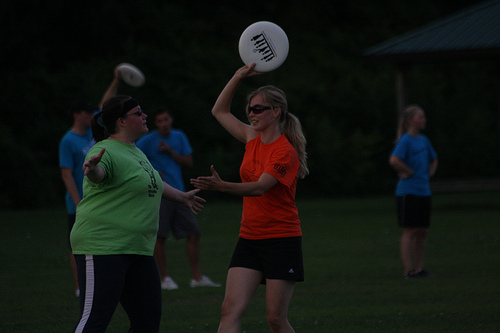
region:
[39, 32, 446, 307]
a group of people playing frisbee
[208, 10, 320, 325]
a girl holding a white frisbee above her head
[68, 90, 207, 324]
a girl in green shirt with her arms out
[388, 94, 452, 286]
a girl with her hands on her hips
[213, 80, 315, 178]
a blonde girl wearing sunglasses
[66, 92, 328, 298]
girl in green shirt blocking girl in the orange shirt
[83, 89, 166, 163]
woman wearing a head band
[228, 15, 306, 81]
white frisbee with black people shapes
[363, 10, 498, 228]
a gazebo made of wood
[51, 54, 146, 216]
a man in blue shirt holding frisbee in the air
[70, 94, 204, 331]
woman in green shirt and black and white pants learning how to play frisby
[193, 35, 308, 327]
woman in orange shirt and black shorts teaching woman how to play frisby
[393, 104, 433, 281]
blond haired girl wearing blue shirt and black shorts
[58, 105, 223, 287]
two guys in the back round both wearing blue shirts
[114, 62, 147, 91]
white frisby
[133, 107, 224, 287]
man wearing blue shirt, grey shorts, and white shoes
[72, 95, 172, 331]
woman in green shirt is wearing a black hairband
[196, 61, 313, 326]
blond woman in orange shirt is wearing sunglasses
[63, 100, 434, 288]
three people in the back round all wearing the same blue tshirt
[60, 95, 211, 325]
woman in green shirt is wearing sunglasses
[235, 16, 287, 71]
White frisbee in hand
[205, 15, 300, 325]
Young Girl on field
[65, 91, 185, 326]
young lady playing frisbee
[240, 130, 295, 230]
girl wearing red Shirt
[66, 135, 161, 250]
Green shirt on a woman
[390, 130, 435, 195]
blue shirt on girl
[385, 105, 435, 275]
Young lady on field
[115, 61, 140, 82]
Frisbee in man's hand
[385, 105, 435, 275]
Person standing on field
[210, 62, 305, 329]
young girl playing frisbee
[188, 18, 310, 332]
a woman holding a Frisbee over her head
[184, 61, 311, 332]
a woman wearing an orange shirt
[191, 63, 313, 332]
a woman wearing shorts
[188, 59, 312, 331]
a woman wearing sunglasses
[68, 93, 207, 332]
a woman wearing a green shirt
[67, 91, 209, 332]
a woman wearing black pants with a white stripe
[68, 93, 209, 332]
a woman wearing a headband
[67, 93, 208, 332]
a woman wearing sunglasses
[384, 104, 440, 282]
a woman standing with her hands on her hips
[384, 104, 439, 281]
a woman wearing a blue shirt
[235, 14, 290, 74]
woman holding white Frisbee with black logo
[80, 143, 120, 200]
woman with outstretched arm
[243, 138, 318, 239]
woman wearing red tee shirt with black logo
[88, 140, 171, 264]
woman wearing green tee shirt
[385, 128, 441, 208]
girl wearing blue tee shirt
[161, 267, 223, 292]
boy wearing pair of white sneakers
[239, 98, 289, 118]
woman wearing wrap a round dark glasses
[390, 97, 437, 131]
girl has long dark blond hair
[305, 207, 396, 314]
neatly trimmed cut green grass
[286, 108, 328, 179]
woman wearing long blond ponytail